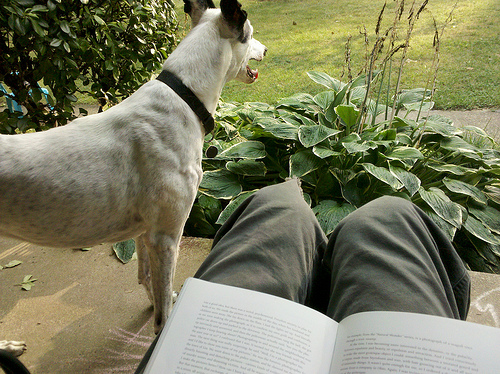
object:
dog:
[0, 0, 267, 336]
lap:
[132, 262, 464, 373]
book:
[144, 276, 497, 373]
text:
[171, 300, 310, 373]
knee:
[230, 182, 319, 249]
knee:
[333, 190, 446, 252]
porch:
[0, 235, 500, 374]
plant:
[190, 70, 500, 271]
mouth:
[244, 56, 263, 84]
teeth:
[252, 68, 259, 71]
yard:
[0, 8, 499, 111]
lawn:
[0, 3, 499, 116]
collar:
[153, 69, 218, 144]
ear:
[219, 0, 248, 27]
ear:
[182, 0, 217, 28]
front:
[128, 132, 203, 336]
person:
[132, 176, 469, 373]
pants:
[126, 180, 468, 372]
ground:
[0, 1, 499, 373]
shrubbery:
[0, 0, 177, 134]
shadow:
[274, 30, 360, 71]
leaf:
[12, 272, 41, 293]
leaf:
[1, 258, 22, 270]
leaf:
[80, 245, 93, 251]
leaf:
[111, 237, 135, 263]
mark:
[472, 287, 500, 327]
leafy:
[200, 67, 499, 272]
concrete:
[0, 235, 495, 372]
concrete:
[0, 279, 95, 373]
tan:
[0, 272, 96, 373]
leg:
[140, 172, 199, 336]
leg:
[134, 231, 178, 301]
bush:
[0, 1, 181, 135]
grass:
[2, 0, 499, 120]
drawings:
[64, 316, 161, 374]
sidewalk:
[372, 107, 499, 149]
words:
[336, 333, 481, 373]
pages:
[146, 276, 338, 373]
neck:
[149, 56, 228, 126]